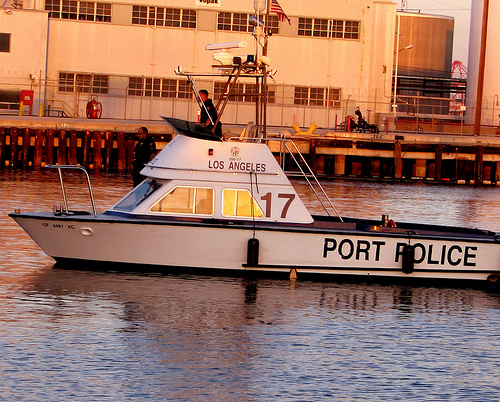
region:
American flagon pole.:
[262, 0, 296, 21]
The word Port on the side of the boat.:
[319, 237, 385, 266]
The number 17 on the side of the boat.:
[262, 190, 308, 217]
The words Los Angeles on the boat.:
[206, 155, 274, 174]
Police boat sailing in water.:
[14, 5, 499, 292]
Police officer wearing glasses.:
[127, 118, 157, 190]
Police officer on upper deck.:
[200, 82, 222, 135]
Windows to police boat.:
[108, 173, 265, 223]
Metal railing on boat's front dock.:
[42, 155, 108, 217]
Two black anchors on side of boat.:
[245, 237, 423, 277]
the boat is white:
[73, 122, 435, 390]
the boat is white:
[107, 40, 298, 285]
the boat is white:
[140, 97, 357, 264]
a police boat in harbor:
[16, 13, 488, 348]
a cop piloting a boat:
[166, 55, 278, 183]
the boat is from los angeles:
[166, 133, 289, 190]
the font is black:
[196, 158, 332, 200]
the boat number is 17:
[221, 147, 333, 237]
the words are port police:
[298, 220, 499, 297]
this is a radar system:
[177, 6, 298, 96]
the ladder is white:
[146, 54, 423, 293]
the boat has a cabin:
[50, 42, 396, 337]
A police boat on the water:
[81, 51, 471, 319]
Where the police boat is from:
[195, 148, 270, 182]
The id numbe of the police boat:
[256, 181, 307, 225]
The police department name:
[315, 226, 496, 275]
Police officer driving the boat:
[158, 54, 285, 135]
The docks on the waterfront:
[19, 53, 454, 165]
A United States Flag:
[250, 4, 320, 38]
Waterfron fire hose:
[77, 91, 116, 118]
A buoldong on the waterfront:
[47, 21, 389, 115]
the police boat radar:
[203, 28, 261, 67]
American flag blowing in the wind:
[271, 1, 288, 23]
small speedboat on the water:
[8, 59, 495, 310]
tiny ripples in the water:
[281, 322, 379, 369]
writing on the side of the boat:
[308, 235, 488, 276]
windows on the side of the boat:
[142, 180, 269, 220]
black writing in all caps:
[320, 233, 476, 272]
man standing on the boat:
[118, 124, 162, 189]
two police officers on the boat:
[106, 87, 231, 189]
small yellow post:
[17, 98, 27, 116]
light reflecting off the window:
[223, 191, 253, 216]